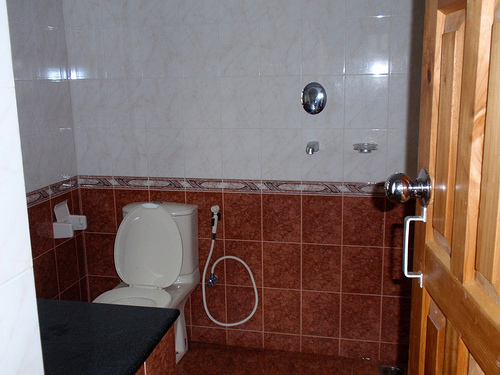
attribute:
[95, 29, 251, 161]
wall — clean, shiny, white, reflecting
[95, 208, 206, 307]
toilet — up, sitting, clean, open, white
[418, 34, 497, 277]
door — brown, open, close, wooden, clean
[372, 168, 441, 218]
knob — silver, metal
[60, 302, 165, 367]
counter — black, clean, dark, close, spotless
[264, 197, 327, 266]
tiles — red 